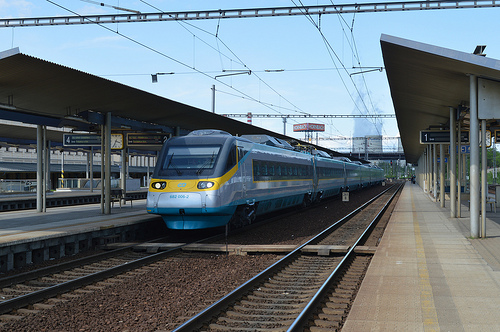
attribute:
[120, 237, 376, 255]
track beam — metal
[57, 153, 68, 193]
pole — metal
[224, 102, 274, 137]
structure — white 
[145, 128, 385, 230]
train — long, yellow, white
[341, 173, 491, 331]
walkway — yellow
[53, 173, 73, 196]
stripes — black and yellow